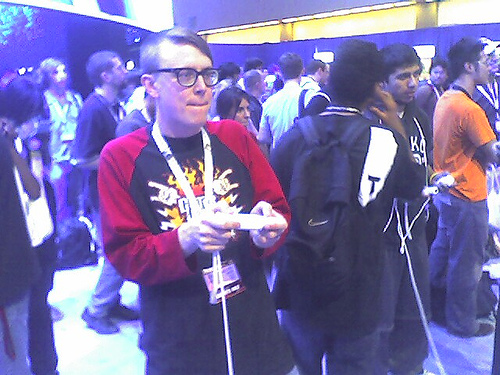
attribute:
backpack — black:
[266, 126, 353, 308]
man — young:
[93, 20, 328, 372]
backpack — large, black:
[288, 114, 373, 304]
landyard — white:
[475, 85, 495, 106]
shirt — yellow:
[426, 92, 490, 187]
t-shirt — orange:
[431, 85, 499, 201]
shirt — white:
[80, 110, 353, 367]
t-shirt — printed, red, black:
[97, 117, 295, 373]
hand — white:
[189, 202, 240, 252]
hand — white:
[248, 199, 288, 247]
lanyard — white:
[145, 120, 252, 302]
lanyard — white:
[145, 120, 226, 241]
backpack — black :
[270, 118, 435, 317]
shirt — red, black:
[92, 115, 295, 373]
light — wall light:
[409, 0, 440, 32]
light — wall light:
[273, 21, 300, 44]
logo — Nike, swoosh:
[306, 215, 331, 227]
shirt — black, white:
[263, 111, 421, 291]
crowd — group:
[15, 24, 497, 350]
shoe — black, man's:
[81, 305, 129, 336]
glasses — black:
[146, 66, 221, 87]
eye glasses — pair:
[146, 65, 226, 87]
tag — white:
[207, 259, 250, 306]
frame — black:
[152, 65, 220, 87]